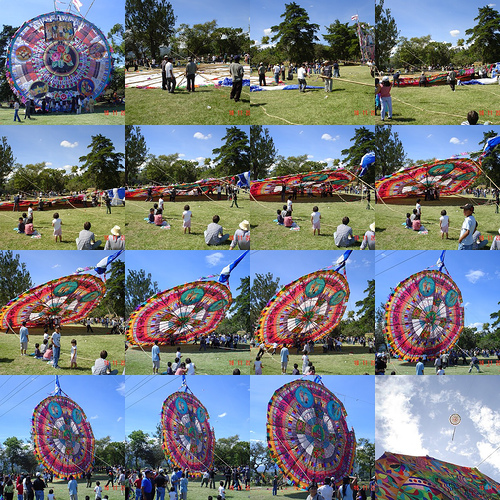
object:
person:
[151, 339, 162, 375]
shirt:
[151, 344, 160, 362]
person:
[279, 342, 291, 375]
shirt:
[279, 346, 289, 363]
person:
[415, 356, 425, 375]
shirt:
[415, 361, 425, 375]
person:
[19, 321, 30, 356]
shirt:
[19, 325, 29, 342]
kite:
[0, 7, 116, 114]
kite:
[124, 270, 233, 347]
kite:
[375, 155, 484, 201]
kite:
[253, 268, 351, 356]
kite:
[380, 267, 466, 365]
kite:
[449, 413, 462, 442]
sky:
[374, 375, 499, 483]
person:
[164, 57, 177, 93]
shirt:
[164, 61, 175, 79]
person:
[297, 64, 309, 93]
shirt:
[297, 67, 307, 80]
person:
[50, 325, 62, 369]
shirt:
[51, 331, 61, 348]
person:
[457, 201, 478, 251]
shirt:
[459, 215, 477, 246]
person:
[273, 63, 281, 83]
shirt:
[273, 65, 281, 74]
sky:
[1, 1, 126, 69]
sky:
[124, 0, 250, 37]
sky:
[250, 0, 376, 48]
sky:
[374, 0, 500, 57]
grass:
[123, 83, 249, 126]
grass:
[250, 64, 375, 125]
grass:
[375, 193, 500, 250]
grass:
[124, 339, 250, 375]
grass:
[374, 353, 500, 375]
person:
[103, 224, 126, 251]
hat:
[110, 225, 121, 236]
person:
[228, 219, 250, 250]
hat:
[238, 219, 250, 231]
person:
[359, 221, 375, 250]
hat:
[368, 221, 375, 232]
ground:
[0, 87, 126, 125]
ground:
[250, 342, 374, 376]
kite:
[0, 264, 109, 330]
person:
[316, 476, 336, 499]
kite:
[264, 377, 356, 494]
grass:
[374, 69, 500, 126]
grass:
[0, 205, 125, 250]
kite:
[160, 386, 217, 475]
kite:
[29, 372, 98, 480]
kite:
[375, 447, 500, 499]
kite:
[250, 166, 360, 201]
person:
[90, 347, 120, 374]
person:
[411, 213, 425, 230]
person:
[333, 215, 361, 248]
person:
[203, 214, 230, 245]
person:
[75, 220, 103, 250]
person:
[281, 204, 288, 218]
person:
[154, 208, 168, 226]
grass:
[125, 192, 249, 250]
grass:
[249, 189, 376, 251]